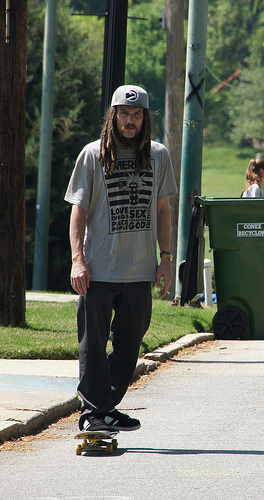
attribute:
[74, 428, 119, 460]
skateboard — wood, yellow, black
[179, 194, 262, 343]
trash can — large, green, black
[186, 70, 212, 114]
black x — painted, graffiti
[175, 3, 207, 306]
pole — metal, grey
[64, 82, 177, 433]
skateboarder — man, skateboarding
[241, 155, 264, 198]
woman — brunette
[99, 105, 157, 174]
dreadlocks — brown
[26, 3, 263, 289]
trees — green, distant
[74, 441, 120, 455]
wheels — yellow, plastic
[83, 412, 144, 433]
shoes — black, white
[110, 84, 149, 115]
cap — grey, black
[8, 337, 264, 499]
street — grey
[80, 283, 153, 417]
pants — black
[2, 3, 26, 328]
power pole — wood